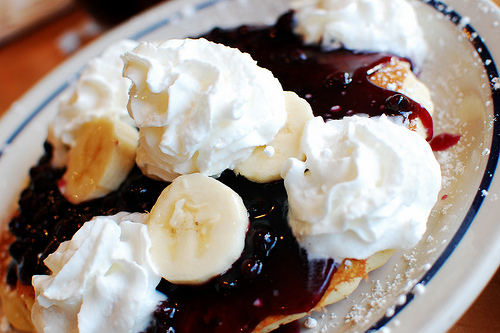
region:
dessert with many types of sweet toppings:
[6, 10, 492, 326]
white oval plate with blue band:
[3, 8, 495, 309]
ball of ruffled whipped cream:
[285, 112, 440, 262]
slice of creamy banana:
[144, 172, 248, 283]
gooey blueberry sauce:
[143, 168, 335, 325]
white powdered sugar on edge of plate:
[417, 15, 493, 283]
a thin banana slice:
[146, 170, 249, 283]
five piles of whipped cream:
[30, 1, 442, 331]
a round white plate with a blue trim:
[1, 4, 498, 330]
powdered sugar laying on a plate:
[2, 0, 499, 331]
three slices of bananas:
[59, 88, 312, 285]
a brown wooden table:
[0, 0, 498, 331]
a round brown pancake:
[1, 28, 433, 328]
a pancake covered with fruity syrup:
[1, 10, 440, 329]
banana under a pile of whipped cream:
[119, 37, 444, 260]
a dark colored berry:
[378, 93, 412, 114]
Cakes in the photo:
[122, 42, 442, 250]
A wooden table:
[2, 17, 64, 72]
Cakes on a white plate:
[15, 17, 477, 329]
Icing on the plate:
[148, 66, 286, 166]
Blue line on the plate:
[464, 50, 497, 228]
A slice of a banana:
[50, 121, 125, 193]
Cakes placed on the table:
[41, 52, 458, 329]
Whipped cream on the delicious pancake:
[107, 27, 294, 183]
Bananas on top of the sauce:
[40, 121, 276, 286]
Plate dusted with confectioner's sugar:
[300, 3, 493, 329]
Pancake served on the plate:
[3, 2, 493, 328]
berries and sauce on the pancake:
[26, 15, 464, 320]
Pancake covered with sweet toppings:
[5, 8, 495, 329]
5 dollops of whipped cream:
[10, 3, 485, 329]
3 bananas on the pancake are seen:
[45, 42, 361, 300]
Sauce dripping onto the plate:
[232, 15, 463, 188]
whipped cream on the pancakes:
[25, 6, 411, 332]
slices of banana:
[55, 118, 243, 277]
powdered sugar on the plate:
[22, 8, 499, 315]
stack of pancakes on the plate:
[2, 24, 420, 321]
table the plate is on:
[5, 11, 498, 327]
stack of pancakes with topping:
[20, 6, 439, 331]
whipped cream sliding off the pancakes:
[297, 0, 417, 65]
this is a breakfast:
[16, 44, 418, 299]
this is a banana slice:
[117, 174, 249, 264]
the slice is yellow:
[155, 183, 306, 284]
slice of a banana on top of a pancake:
[142, 173, 247, 288]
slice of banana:
[145, 177, 247, 281]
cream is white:
[305, 147, 415, 235]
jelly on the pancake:
[256, 248, 321, 292]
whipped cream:
[313, 122, 419, 232]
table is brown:
[12, 49, 45, 76]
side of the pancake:
[331, 267, 361, 299]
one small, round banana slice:
[145, 173, 251, 283]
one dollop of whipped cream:
[285, 114, 443, 254]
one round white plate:
[0, 2, 498, 328]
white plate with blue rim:
[1, 1, 498, 331]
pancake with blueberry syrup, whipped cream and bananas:
[2, 4, 441, 328]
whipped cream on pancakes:
[30, 0, 442, 331]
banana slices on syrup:
[59, 87, 315, 285]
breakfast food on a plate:
[0, 1, 498, 326]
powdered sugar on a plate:
[341, 208, 486, 332]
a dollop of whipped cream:
[307, 125, 435, 250]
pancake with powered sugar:
[386, 62, 410, 87]